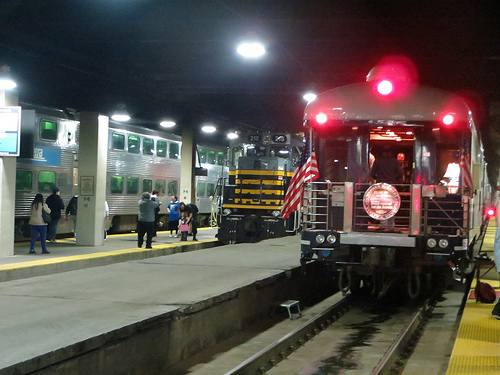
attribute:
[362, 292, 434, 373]
rails — metal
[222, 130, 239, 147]
light — white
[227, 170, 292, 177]
stripe — yellow and black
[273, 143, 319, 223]
flag — american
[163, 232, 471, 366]
track — metal, railway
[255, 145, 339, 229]
flag — American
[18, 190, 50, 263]
woman jacket — white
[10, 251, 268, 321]
platform — train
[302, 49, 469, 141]
lights — red, brake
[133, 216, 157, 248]
pants — black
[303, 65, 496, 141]
lights — red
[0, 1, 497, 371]
station — railway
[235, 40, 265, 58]
light — white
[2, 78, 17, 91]
light — white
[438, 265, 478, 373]
edge — yellow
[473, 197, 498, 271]
edge — yellow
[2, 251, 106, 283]
edge — yellow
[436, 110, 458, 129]
headlights — red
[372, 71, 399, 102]
headlights — red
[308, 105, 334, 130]
headlights — red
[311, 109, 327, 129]
light — red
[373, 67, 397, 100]
light — red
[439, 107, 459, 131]
light — red